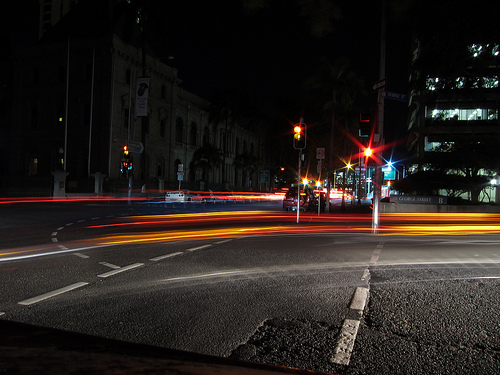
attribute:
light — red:
[352, 131, 383, 172]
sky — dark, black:
[82, 17, 449, 125]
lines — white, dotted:
[48, 217, 394, 342]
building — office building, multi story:
[403, 20, 498, 201]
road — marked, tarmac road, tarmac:
[1, 211, 498, 373]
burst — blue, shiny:
[376, 150, 405, 180]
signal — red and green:
[109, 157, 146, 182]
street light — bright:
[290, 120, 307, 135]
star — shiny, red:
[347, 127, 394, 184]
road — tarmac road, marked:
[293, 250, 388, 298]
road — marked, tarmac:
[366, 233, 446, 286]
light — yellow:
[91, 226, 498, 249]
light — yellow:
[74, 225, 499, 242]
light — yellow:
[122, 208, 497, 220]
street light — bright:
[284, 110, 316, 160]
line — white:
[322, 215, 398, 373]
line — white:
[6, 195, 178, 262]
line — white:
[15, 220, 258, 341]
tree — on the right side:
[404, 119, 467, 214]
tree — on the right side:
[463, 112, 498, 197]